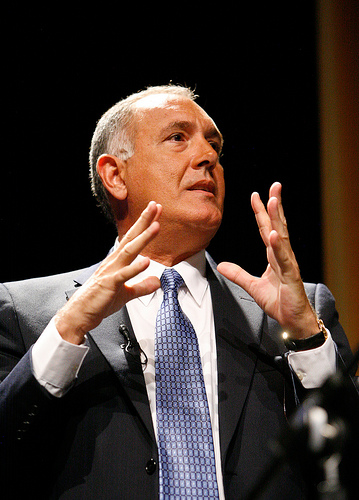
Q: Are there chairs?
A: No, there are no chairs.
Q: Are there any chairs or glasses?
A: No, there are no chairs or glasses.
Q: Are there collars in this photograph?
A: Yes, there is a collar.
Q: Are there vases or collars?
A: Yes, there is a collar.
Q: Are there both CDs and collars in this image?
A: No, there is a collar but no cds.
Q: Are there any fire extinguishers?
A: No, there are no fire extinguishers.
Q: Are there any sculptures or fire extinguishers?
A: No, there are no fire extinguishers or sculptures.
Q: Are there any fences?
A: No, there are no fences.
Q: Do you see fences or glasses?
A: No, there are no fences or glasses.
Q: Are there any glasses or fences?
A: No, there are no fences or glasses.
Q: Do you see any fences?
A: No, there are no fences.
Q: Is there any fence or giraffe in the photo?
A: No, there are no fences or giraffes.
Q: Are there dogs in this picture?
A: No, there are no dogs.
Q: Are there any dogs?
A: No, there are no dogs.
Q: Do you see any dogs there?
A: No, there are no dogs.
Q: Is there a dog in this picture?
A: No, there are no dogs.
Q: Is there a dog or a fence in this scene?
A: No, there are no dogs or fences.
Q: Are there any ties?
A: Yes, there is a tie.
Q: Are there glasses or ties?
A: Yes, there is a tie.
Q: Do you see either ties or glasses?
A: Yes, there is a tie.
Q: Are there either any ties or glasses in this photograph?
A: Yes, there is a tie.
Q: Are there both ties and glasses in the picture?
A: No, there is a tie but no glasses.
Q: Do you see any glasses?
A: No, there are no glasses.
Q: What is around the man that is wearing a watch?
A: The necktie is around the man.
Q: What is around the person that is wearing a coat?
A: The necktie is around the man.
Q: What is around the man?
A: The necktie is around the man.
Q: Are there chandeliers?
A: No, there are no chandeliers.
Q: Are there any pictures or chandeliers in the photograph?
A: No, there are no chandeliers or pictures.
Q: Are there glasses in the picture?
A: No, there are no glasses.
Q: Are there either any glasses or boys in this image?
A: No, there are no glasses or boys.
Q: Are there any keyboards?
A: No, there are no keyboards.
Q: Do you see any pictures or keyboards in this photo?
A: No, there are no keyboards or pictures.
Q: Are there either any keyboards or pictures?
A: No, there are no keyboards or pictures.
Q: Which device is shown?
A: The device is a screen.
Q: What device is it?
A: The device is a screen.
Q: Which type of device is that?
A: This is a screen.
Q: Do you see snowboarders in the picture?
A: No, there are no snowboarders.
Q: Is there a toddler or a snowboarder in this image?
A: No, there are no snowboarders or toddlers.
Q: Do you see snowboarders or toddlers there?
A: No, there are no snowboarders or toddlers.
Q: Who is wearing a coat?
A: The man is wearing a coat.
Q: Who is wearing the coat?
A: The man is wearing a coat.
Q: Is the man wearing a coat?
A: Yes, the man is wearing a coat.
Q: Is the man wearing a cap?
A: No, the man is wearing a coat.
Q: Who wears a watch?
A: The man wears a watch.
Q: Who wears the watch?
A: The man wears a watch.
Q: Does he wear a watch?
A: Yes, the man wears a watch.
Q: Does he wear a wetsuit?
A: No, the man wears a watch.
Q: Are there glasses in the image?
A: No, there are no glasses.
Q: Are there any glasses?
A: No, there are no glasses.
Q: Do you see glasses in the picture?
A: No, there are no glasses.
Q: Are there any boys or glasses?
A: No, there are no glasses or boys.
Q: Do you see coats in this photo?
A: Yes, there is a coat.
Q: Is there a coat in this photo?
A: Yes, there is a coat.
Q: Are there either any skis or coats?
A: Yes, there is a coat.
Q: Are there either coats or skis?
A: Yes, there is a coat.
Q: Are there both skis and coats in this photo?
A: No, there is a coat but no skis.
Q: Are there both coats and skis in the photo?
A: No, there is a coat but no skis.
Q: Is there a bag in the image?
A: No, there are no bags.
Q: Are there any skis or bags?
A: No, there are no bags or skis.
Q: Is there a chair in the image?
A: No, there are no chairs.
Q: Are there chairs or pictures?
A: No, there are no chairs or pictures.